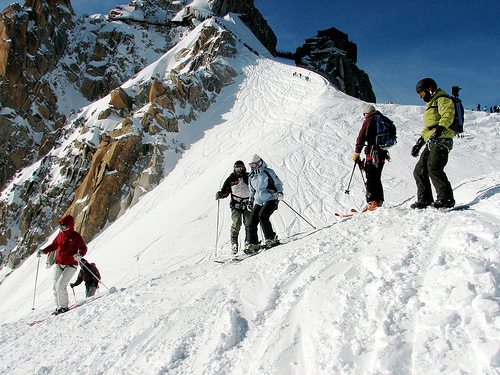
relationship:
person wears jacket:
[246, 154, 284, 254] [249, 164, 282, 202]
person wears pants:
[246, 154, 284, 254] [244, 198, 282, 243]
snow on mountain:
[50, 4, 206, 101] [4, 12, 359, 180]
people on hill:
[29, 72, 473, 325] [17, 64, 489, 368]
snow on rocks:
[5, 26, 304, 186] [0, 0, 237, 277]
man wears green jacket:
[410, 78, 464, 210] [411, 96, 459, 147]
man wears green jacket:
[410, 78, 464, 210] [421, 87, 455, 143]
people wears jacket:
[37, 215, 87, 316] [43, 215, 86, 265]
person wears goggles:
[244, 153, 284, 253] [247, 162, 262, 167]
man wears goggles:
[215, 160, 252, 255] [233, 165, 243, 172]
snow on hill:
[12, 10, 209, 240] [0, 0, 500, 375]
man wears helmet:
[407, 71, 472, 214] [407, 79, 448, 104]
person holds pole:
[353, 101, 394, 218] [342, 156, 358, 197]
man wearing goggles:
[215, 160, 252, 255] [236, 166, 244, 170]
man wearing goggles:
[215, 160, 252, 255] [248, 161, 263, 168]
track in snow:
[203, 85, 249, 162] [0, 0, 499, 373]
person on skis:
[353, 104, 398, 212] [329, 197, 396, 220]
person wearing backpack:
[353, 104, 398, 212] [370, 110, 400, 148]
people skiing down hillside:
[37, 215, 87, 316] [1, 104, 500, 373]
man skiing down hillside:
[215, 160, 252, 255] [1, 104, 500, 373]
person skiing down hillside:
[244, 153, 284, 253] [1, 104, 500, 373]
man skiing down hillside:
[410, 78, 464, 210] [1, 104, 500, 373]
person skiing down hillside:
[353, 104, 398, 212] [1, 104, 500, 373]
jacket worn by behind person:
[247, 175, 272, 192] [246, 154, 284, 254]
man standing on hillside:
[410, 78, 464, 210] [1, 166, 495, 373]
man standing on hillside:
[353, 104, 397, 212] [1, 166, 495, 373]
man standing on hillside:
[217, 158, 256, 255] [1, 166, 495, 373]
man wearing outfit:
[335, 106, 415, 204] [348, 119, 419, 169]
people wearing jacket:
[37, 215, 87, 316] [38, 226, 88, 266]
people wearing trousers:
[37, 215, 87, 316] [52, 262, 76, 310]